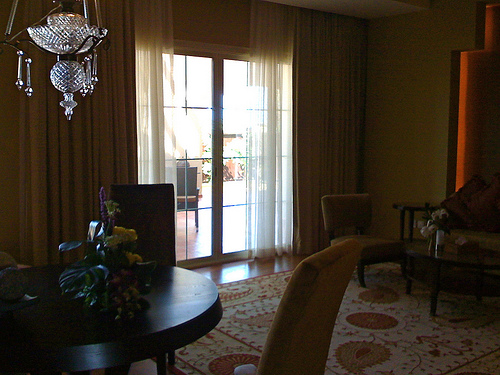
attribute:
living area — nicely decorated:
[8, 7, 497, 374]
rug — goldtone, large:
[154, 259, 494, 375]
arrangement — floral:
[54, 198, 153, 318]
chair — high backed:
[254, 237, 361, 375]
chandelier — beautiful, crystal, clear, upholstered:
[8, 7, 112, 127]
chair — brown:
[318, 184, 404, 279]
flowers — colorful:
[65, 181, 154, 330]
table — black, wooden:
[138, 276, 225, 363]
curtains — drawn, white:
[124, 14, 302, 279]